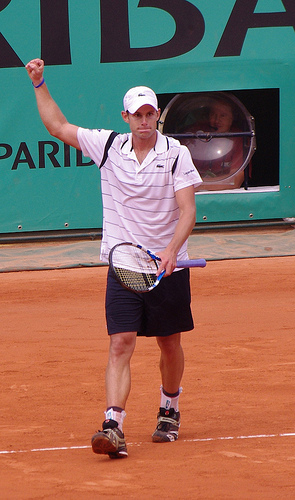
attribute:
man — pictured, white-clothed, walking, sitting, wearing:
[42, 35, 261, 472]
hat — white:
[121, 78, 173, 111]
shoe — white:
[75, 374, 204, 450]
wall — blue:
[30, 10, 223, 122]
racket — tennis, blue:
[41, 229, 219, 317]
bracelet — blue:
[15, 54, 62, 116]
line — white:
[23, 418, 86, 465]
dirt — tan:
[95, 457, 131, 482]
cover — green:
[63, 56, 107, 114]